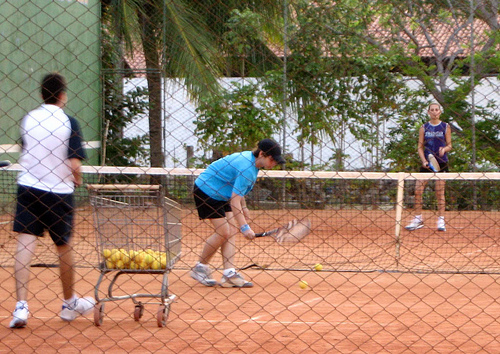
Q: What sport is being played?
A: Tennis.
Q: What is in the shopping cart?
A: Tennis balls.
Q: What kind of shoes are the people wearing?
A: Tennis shoes.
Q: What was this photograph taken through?
A: A chain linked fence.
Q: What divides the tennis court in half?
A: A net.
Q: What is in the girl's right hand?
A: A tennis racquet.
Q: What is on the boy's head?
A: A black cap.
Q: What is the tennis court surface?
A: Clay.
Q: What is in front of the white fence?
A: Foliage.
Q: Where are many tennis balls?
A: In a cart.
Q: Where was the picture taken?
A: At a tennis court.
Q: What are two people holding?
A: Tennis rackets.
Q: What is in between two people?
A: A net.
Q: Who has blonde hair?
A: Woman in purple.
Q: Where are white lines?
A: On the court.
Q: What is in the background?
A: Trees.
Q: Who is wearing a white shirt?
A: Person on left.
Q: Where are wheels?
A: Under the cart.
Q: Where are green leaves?
A: On trees.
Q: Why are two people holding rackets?
A: To play tennis.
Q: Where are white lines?
A: On the court.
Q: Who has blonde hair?
A: Woman in purple shirt.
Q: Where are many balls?
A: In a cart.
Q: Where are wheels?
A: Under the cart.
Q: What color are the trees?
A: Green.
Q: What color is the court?
A: Clay.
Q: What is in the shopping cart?
A: Tennis balls.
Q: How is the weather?
A: Clear.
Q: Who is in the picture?
A: Two women and a man.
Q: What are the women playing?
A: Tennis.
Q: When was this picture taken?
A: Daytime.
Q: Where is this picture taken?
A: A tennis court.